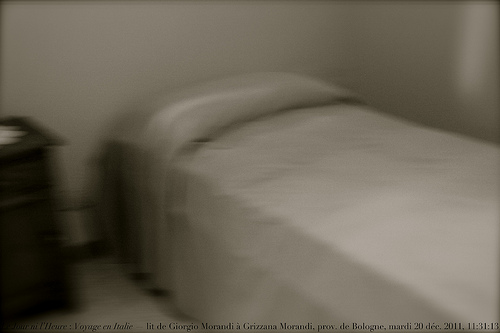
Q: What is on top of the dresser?
A: A doily.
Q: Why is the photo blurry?
A: Someone moved when taking the picture.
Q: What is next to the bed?
A: A brown desk.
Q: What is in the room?
A: Bed and desk.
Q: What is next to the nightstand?
A: A bed.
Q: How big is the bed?
A: A twin size.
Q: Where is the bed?
A: In a white room.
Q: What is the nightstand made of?
A: Wood.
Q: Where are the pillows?
A: At the head of the bed.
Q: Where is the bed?
A: In a small room.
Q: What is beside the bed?
A: Dresser.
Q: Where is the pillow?
A: On the bed.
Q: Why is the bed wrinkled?
A: Someone slept in it.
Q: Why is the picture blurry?
A: Camera was moving.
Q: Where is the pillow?
A: Bed.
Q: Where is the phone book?
A: Nightstand.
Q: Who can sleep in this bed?
A: One person.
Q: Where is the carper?
A: On the ground.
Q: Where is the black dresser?
A: Near the bed.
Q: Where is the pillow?
A: Under sheet.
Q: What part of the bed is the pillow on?
A: Head.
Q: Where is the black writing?
A: Bottom.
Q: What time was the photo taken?
A: 11:31:13.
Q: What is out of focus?
A: The photo itself.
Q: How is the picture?
A: Blurry.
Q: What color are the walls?
A: White.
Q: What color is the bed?
A: Cream.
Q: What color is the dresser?
A: Brown.